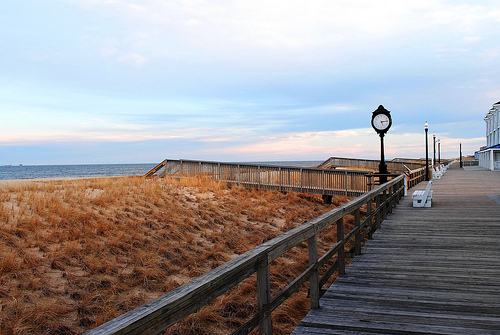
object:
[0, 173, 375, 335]
sand dune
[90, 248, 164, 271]
dried grass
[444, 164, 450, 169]
bench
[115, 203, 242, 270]
grass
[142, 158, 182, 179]
stairway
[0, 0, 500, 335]
field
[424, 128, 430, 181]
lamp post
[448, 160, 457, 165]
benches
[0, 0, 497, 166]
sky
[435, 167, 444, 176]
bench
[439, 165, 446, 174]
bench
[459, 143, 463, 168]
post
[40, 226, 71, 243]
brush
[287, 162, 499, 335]
boardwalk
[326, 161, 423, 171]
boardwalk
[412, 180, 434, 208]
bench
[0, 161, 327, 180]
ocean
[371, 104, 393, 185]
clock tower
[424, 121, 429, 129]
lights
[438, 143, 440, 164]
pole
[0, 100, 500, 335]
pier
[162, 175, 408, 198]
boardwalk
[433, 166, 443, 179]
bench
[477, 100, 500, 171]
building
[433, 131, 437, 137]
street light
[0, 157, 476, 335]
beach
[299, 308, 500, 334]
slats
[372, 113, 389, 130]
clock